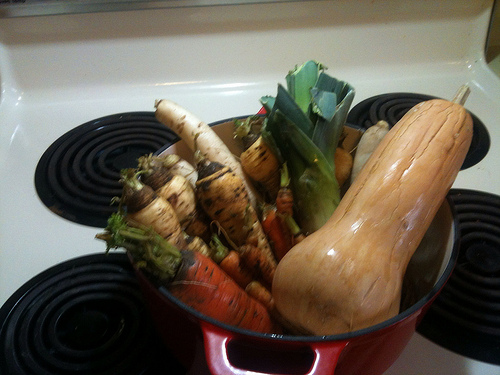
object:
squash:
[271, 88, 481, 333]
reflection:
[160, 62, 268, 102]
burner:
[352, 87, 489, 169]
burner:
[6, 246, 205, 373]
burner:
[415, 187, 498, 364]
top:
[100, 215, 177, 286]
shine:
[322, 220, 376, 279]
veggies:
[279, 202, 304, 240]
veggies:
[100, 210, 180, 282]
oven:
[5, 6, 493, 373]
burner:
[35, 112, 193, 231]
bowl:
[110, 104, 459, 370]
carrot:
[91, 217, 281, 336]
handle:
[192, 327, 342, 375]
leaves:
[266, 60, 356, 206]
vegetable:
[269, 61, 472, 331]